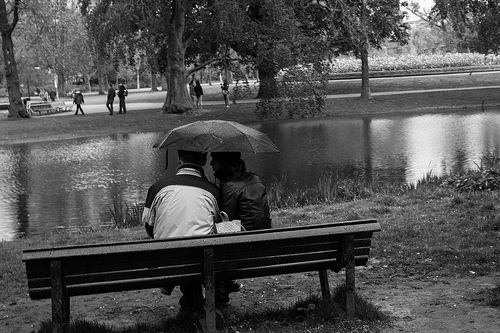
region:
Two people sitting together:
[0, 112, 392, 317]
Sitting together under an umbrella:
[122, 102, 295, 267]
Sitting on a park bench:
[127, 107, 308, 331]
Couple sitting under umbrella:
[130, 116, 282, 233]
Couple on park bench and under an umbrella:
[110, 98, 300, 324]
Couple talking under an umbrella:
[135, 115, 282, 287]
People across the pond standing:
[62, 62, 258, 120]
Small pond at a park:
[350, 87, 475, 199]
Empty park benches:
[25, 97, 67, 113]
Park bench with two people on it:
[0, 184, 388, 331]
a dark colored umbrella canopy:
[153, 119, 280, 157]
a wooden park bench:
[21, 215, 381, 330]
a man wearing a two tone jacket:
[141, 167, 224, 237]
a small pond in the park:
[280, 100, 498, 183]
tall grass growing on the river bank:
[275, 150, 496, 215]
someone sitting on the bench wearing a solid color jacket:
[221, 171, 273, 229]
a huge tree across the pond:
[158, 0, 203, 113]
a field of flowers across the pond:
[369, 50, 498, 70]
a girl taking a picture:
[219, 78, 231, 109]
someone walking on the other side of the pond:
[72, 86, 86, 115]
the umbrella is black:
[161, 112, 278, 167]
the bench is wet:
[30, 220, 380, 310]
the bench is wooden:
[25, 230, 405, 315]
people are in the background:
[63, 67, 149, 109]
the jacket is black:
[227, 172, 286, 223]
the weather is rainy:
[7, 20, 492, 331]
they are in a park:
[118, 111, 304, 296]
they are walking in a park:
[60, 82, 144, 121]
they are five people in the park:
[44, 58, 274, 115]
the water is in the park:
[20, 100, 497, 201]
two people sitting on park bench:
[8, 15, 456, 306]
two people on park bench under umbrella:
[3, 47, 452, 305]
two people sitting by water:
[1, 8, 494, 327]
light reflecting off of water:
[0, 45, 494, 271]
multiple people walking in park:
[0, 11, 306, 116]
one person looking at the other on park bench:
[1, 106, 403, 298]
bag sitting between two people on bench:
[3, 114, 424, 325]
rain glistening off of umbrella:
[44, 105, 399, 325]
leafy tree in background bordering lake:
[15, 3, 457, 155]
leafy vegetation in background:
[244, 3, 486, 84]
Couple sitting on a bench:
[108, 98, 324, 304]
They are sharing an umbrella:
[134, 93, 288, 220]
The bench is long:
[16, 198, 408, 323]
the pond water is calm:
[322, 95, 487, 187]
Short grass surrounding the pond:
[367, 185, 485, 254]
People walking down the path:
[66, 66, 164, 111]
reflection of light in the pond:
[377, 100, 479, 180]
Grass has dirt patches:
[375, 252, 462, 324]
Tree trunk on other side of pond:
[335, 26, 391, 93]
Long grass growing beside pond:
[291, 155, 406, 222]